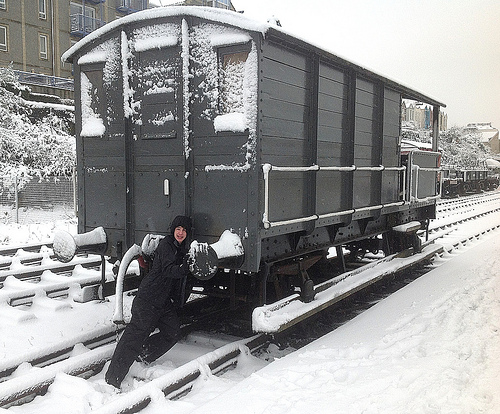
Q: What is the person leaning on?
A: A train car.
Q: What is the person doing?
A: Pushing a train car.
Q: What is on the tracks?
A: A train car.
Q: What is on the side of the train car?
A: Railings.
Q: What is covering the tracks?
A: Snow.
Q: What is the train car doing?
A: Parked.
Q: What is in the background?
A: Building.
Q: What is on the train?
A: Snow.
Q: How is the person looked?
A: Snowsuit.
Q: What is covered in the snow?
A: Train car.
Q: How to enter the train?
A: Door.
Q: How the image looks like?
A: Chilling.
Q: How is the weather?
A: Snowing.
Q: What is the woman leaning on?
A: The car of a train.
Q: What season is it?
A: Winter.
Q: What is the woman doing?
A: Pretend to push the train car.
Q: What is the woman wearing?
A: Pants and a black coat.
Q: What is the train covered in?
A: Snow.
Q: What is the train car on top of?
A: Train tracks.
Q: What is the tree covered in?
A: Snow.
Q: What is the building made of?
A: Bricks.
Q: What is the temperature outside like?
A: Cold.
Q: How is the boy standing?
A: Leaning.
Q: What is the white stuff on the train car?
A: Snow.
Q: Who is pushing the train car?
A: The boy.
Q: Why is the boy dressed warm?
A: Because of snow.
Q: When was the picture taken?
A: Winter.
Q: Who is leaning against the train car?
A: A boy.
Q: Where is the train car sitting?
A: On tracks.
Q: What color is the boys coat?
A: Black.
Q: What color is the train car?
A: Charcoal Gray.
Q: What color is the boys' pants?
A: Black.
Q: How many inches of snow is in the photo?
A: 3 inches.